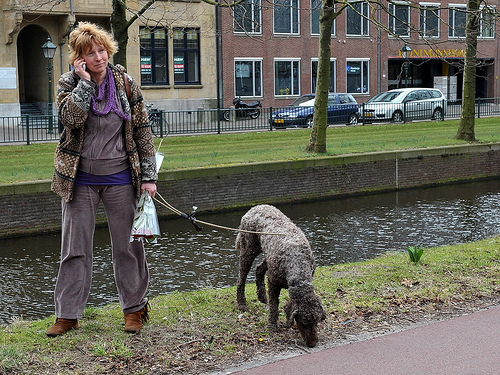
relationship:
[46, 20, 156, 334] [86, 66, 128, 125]
woman wearing scarf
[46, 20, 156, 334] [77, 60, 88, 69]
woman talking on cell phone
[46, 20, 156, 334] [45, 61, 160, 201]
woman wearing jogging suit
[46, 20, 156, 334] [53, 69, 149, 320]
woman wearing jogging suit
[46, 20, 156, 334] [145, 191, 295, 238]
woman holding leash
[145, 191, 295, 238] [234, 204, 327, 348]
leash attached to dog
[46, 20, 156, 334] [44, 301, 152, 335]
woman wearing boots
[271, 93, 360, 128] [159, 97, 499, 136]
car parked on street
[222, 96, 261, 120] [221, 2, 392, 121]
motorcycle next to wall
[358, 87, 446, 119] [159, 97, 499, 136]
van park on street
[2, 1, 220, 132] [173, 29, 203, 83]
building has window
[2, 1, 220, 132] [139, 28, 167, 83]
building has window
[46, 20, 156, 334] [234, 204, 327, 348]
woman walking dog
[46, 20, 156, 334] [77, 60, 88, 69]
woman holding cell phone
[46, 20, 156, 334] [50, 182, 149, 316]
woman wearing pants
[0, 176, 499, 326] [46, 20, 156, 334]
canal behind woman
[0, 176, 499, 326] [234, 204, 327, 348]
canal behind dog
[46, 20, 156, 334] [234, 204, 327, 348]
woman next to dog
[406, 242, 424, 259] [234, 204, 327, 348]
plant to right of dog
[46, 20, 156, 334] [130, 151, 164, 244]
woman holding paper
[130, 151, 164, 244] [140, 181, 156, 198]
paper held in hand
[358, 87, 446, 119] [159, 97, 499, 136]
van parked on street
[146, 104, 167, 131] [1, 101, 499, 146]
bike behind fence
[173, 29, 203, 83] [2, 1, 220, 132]
window on building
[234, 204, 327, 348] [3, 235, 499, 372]
dog foraging on ground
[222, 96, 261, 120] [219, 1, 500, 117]
motorcycle near building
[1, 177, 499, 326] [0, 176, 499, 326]
water inside canal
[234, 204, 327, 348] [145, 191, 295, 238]
dog wearing leash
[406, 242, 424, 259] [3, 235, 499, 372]
plant growing on ground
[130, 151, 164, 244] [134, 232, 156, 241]
paper around flowers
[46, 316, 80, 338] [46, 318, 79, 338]
boot on right foot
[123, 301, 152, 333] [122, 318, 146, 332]
boot worn on left foot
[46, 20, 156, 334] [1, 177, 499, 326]
woman standing near water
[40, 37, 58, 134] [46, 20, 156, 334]
lightpost behind woman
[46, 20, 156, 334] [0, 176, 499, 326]
woman standing near canal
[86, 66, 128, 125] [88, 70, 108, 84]
scarf around neck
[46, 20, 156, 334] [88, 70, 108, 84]
woman has neck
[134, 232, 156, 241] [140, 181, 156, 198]
flowers held in left hand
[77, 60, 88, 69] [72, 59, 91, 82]
cell phone held in left hand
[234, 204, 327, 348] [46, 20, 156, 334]
dog standing next to woman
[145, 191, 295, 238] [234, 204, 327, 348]
leash hanging on dog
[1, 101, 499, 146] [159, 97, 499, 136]
fence along street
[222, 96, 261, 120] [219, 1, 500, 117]
motorcycle parked near building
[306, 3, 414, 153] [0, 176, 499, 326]
tree behind canal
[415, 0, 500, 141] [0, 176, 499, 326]
tree behind canal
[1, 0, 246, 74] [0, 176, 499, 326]
tree behind canal